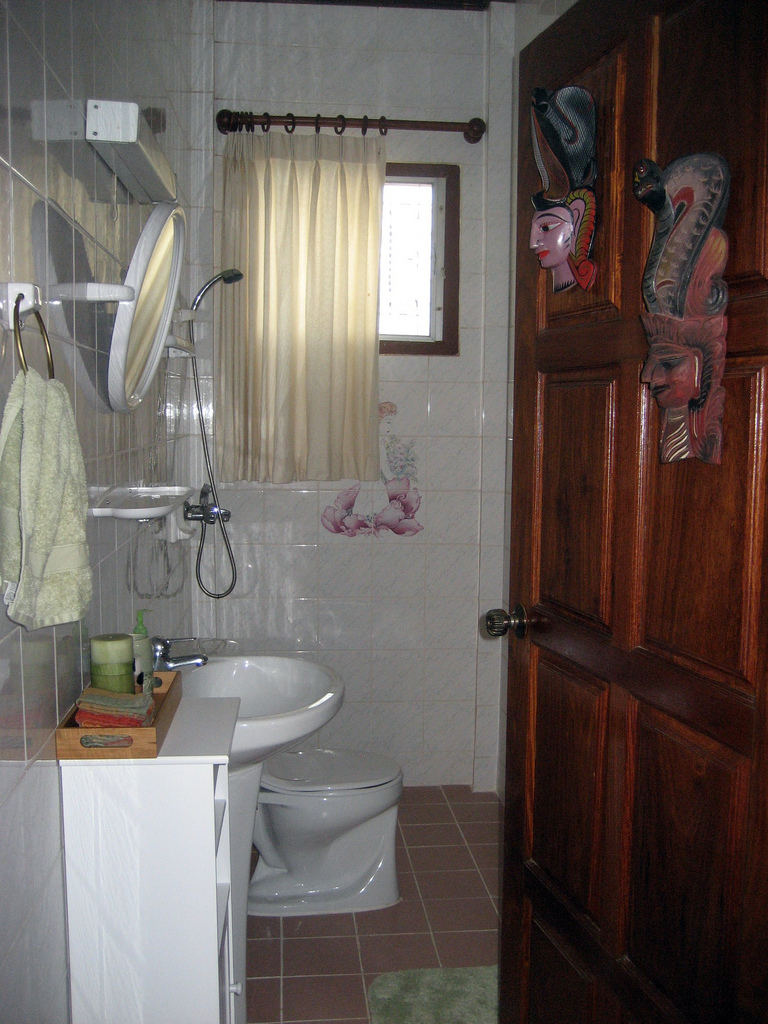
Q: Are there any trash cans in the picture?
A: No, there are no trash cans.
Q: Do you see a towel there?
A: Yes, there is a towel.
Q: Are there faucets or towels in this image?
A: Yes, there is a towel.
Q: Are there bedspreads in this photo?
A: No, there are no bedspreads.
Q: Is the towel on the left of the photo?
A: Yes, the towel is on the left of the image.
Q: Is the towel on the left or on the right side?
A: The towel is on the left of the image.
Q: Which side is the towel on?
A: The towel is on the left of the image.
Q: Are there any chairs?
A: No, there are no chairs.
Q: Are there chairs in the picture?
A: No, there are no chairs.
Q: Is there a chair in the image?
A: No, there are no chairs.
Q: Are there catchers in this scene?
A: No, there are no catchers.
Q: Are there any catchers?
A: No, there are no catchers.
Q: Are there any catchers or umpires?
A: No, there are no catchers or umpires.